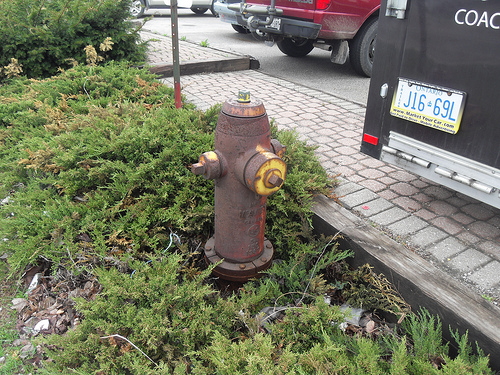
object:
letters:
[403, 91, 455, 121]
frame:
[454, 8, 467, 25]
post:
[170, 0, 182, 107]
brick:
[139, 32, 499, 299]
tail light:
[315, 0, 329, 10]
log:
[329, 265, 479, 346]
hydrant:
[193, 90, 289, 285]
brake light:
[362, 132, 379, 146]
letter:
[464, 10, 479, 26]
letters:
[453, 9, 499, 30]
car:
[357, 1, 497, 211]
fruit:
[191, 89, 288, 281]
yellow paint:
[255, 159, 286, 194]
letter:
[411, 92, 417, 110]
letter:
[417, 94, 426, 113]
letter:
[433, 98, 443, 116]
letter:
[441, 100, 450, 118]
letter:
[403, 91, 412, 108]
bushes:
[0, 0, 499, 375]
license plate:
[389, 76, 467, 134]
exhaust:
[313, 39, 333, 51]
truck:
[211, 0, 380, 78]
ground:
[0, 77, 500, 375]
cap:
[253, 158, 287, 195]